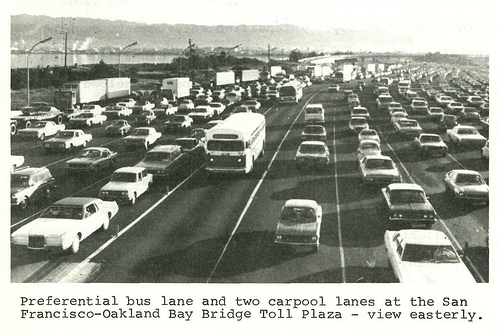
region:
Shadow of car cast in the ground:
[130, 213, 280, 277]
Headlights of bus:
[200, 153, 250, 165]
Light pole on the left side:
[18, 29, 62, 110]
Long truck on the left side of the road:
[55, 68, 140, 114]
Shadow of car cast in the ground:
[324, 200, 383, 253]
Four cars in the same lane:
[278, 94, 346, 269]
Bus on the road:
[275, 76, 308, 113]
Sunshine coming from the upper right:
[354, 5, 493, 58]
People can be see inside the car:
[283, 205, 317, 219]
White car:
[6, 188, 132, 266]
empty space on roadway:
[162, 186, 237, 283]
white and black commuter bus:
[197, 108, 275, 202]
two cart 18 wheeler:
[59, 72, 144, 103]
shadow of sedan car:
[151, 219, 281, 285]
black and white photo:
[36, 14, 445, 274]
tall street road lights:
[20, 27, 90, 113]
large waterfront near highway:
[47, 44, 171, 63]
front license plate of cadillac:
[23, 231, 58, 257]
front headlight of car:
[394, 209, 435, 221]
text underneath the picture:
[17, 289, 498, 320]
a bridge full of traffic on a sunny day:
[12, 68, 494, 283]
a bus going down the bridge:
[203, 107, 264, 177]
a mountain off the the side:
[11, 12, 318, 54]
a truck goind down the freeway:
[56, 78, 138, 100]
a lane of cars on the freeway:
[331, 92, 458, 303]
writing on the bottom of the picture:
[10, 285, 487, 331]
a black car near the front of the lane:
[376, 180, 434, 222]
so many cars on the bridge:
[331, 65, 478, 114]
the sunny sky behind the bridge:
[371, 26, 481, 54]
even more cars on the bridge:
[33, 105, 188, 185]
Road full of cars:
[16, 55, 498, 285]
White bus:
[192, 99, 274, 185]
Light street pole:
[18, 26, 60, 101]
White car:
[371, 217, 486, 289]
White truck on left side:
[44, 69, 142, 116]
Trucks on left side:
[193, 53, 297, 86]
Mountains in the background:
[10, 5, 442, 55]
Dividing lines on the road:
[205, 170, 270, 265]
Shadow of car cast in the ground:
[273, 163, 363, 203]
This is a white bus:
[173, 96, 286, 192]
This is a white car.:
[14, 190, 123, 259]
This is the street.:
[178, 226, 210, 256]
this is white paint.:
[202, 219, 247, 264]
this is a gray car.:
[275, 185, 330, 257]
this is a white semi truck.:
[56, 77, 132, 112]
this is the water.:
[28, 47, 84, 66]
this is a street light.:
[113, 40, 142, 79]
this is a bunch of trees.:
[173, 42, 236, 70]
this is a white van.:
[301, 99, 338, 124]